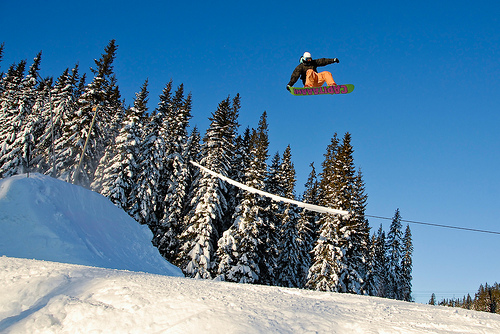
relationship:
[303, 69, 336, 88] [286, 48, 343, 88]
pants on snowboarder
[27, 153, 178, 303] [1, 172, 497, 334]
snow on mountain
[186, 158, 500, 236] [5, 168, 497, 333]
powerline with snow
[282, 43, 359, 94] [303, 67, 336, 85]
man wearing pant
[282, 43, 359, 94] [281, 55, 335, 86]
man wearing jacket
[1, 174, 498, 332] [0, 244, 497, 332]
white snow on ground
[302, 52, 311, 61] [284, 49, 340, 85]
hat on a snowboarder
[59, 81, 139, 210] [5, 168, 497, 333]
pole sticking out of snow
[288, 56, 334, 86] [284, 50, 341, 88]
black coat on snowboarder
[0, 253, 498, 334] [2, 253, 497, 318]
snow covering ground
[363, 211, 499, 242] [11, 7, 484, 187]
black wire in sky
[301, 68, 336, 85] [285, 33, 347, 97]
pants on snowboarder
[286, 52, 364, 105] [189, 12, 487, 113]
snowboarder in air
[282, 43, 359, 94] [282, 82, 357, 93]
man on snowboard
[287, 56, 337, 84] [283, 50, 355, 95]
black coat on snowboarder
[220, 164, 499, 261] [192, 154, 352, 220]
powerline partially covered with ice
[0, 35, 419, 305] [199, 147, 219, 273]
tree covered in snow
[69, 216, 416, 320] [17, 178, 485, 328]
snow covering ground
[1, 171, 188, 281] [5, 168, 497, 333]
hill of snow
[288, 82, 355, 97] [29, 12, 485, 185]
drsnowboard flying through air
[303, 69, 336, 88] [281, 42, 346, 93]
pants on person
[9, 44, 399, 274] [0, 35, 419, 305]
grove of tree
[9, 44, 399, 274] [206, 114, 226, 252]
grove of tree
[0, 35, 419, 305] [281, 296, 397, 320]
tree with snow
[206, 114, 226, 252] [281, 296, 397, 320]
tree with snow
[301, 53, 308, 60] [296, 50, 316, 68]
hat on head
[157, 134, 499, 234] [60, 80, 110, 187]
wire hanging from pole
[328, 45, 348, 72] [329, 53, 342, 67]
glove on hand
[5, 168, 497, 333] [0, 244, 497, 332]
snow all over ground